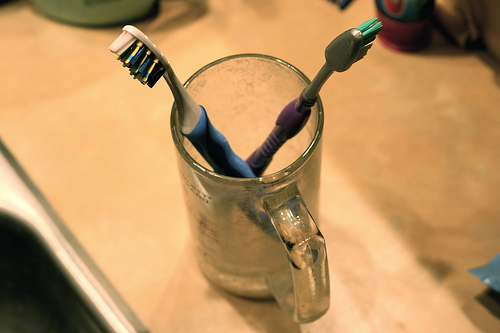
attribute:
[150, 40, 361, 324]
mug — glass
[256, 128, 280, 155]
stripe — purple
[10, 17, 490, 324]
table — wood, wooden, brown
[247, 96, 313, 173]
rubber — handle, purple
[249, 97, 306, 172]
purple handle — rubber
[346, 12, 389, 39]
bristles — blue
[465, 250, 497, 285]
paper — blue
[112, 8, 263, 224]
toothbrush — blue, yellow, and white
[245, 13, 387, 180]
toothbrush — purple and copper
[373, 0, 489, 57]
bottle — red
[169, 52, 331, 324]
mug — clear, glass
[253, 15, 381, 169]
toothbrush — purple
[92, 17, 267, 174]
toothbrush — purple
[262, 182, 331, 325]
handle — glass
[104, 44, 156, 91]
bristles — white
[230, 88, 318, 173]
handle — purple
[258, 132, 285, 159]
stripe — purple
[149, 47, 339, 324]
cup — glass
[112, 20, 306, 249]
toothbrush — blue